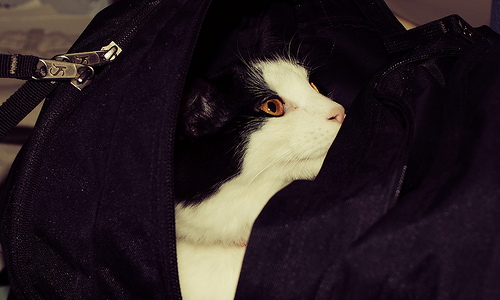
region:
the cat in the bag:
[166, 50, 351, 197]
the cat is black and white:
[152, 45, 368, 283]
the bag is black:
[40, 7, 496, 298]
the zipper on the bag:
[26, 53, 99, 94]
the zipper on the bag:
[45, 47, 127, 66]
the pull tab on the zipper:
[2, 55, 36, 77]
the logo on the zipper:
[41, 59, 74, 81]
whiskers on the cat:
[225, 127, 329, 174]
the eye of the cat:
[247, 90, 301, 127]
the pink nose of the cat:
[316, 103, 352, 125]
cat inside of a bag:
[151, 49, 357, 248]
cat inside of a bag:
[156, 110, 291, 296]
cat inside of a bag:
[216, 20, 438, 152]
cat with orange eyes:
[261, 93, 287, 121]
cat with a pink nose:
[321, 99, 345, 121]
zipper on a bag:
[37, 42, 116, 93]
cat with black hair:
[178, 91, 237, 151]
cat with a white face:
[260, 62, 342, 142]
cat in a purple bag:
[66, 77, 343, 285]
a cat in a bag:
[6, 0, 491, 295]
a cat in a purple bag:
[5, 0, 495, 290]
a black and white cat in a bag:
[10, 0, 490, 290]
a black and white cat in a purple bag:
[15, 0, 487, 290]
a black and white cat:
[167, 14, 347, 297]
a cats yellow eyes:
[245, 78, 327, 136]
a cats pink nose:
[326, 105, 348, 132]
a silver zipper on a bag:
[17, 36, 122, 94]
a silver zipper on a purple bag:
[2, 19, 141, 119]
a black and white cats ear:
[166, 71, 216, 138]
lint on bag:
[41, 153, 87, 202]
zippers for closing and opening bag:
[1, 40, 122, 130]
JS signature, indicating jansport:
[49, 58, 67, 79]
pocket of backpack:
[163, 0, 425, 297]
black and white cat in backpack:
[167, 40, 347, 298]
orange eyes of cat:
[254, 95, 285, 116]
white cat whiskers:
[256, 134, 320, 174]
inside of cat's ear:
[181, 93, 215, 125]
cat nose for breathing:
[316, 102, 346, 127]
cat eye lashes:
[286, 33, 321, 76]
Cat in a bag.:
[163, 12, 390, 282]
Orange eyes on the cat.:
[206, 54, 331, 124]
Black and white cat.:
[171, 42, 396, 226]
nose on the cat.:
[303, 81, 369, 141]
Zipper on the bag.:
[17, 27, 112, 117]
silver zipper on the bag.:
[19, 0, 169, 120]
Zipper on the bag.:
[371, 8, 483, 144]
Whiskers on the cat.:
[231, 32, 333, 190]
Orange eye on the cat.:
[241, 63, 300, 140]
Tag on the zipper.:
[1, 43, 74, 103]